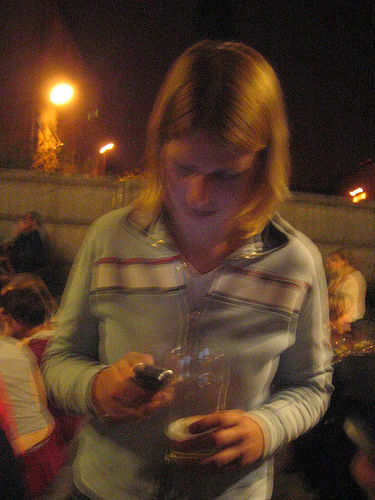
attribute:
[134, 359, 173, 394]
phone — silver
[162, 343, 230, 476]
glass — beer, held, small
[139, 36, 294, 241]
hair — blonde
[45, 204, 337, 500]
shirt — blue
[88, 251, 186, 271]
stripes — red, white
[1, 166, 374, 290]
fence — wooden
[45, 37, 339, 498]
person — sitting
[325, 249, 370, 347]
person — walking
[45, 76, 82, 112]
light — yellow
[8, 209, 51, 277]
guy — walking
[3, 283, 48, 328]
hair — brown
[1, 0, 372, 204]
sky — black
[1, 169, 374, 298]
wall — grey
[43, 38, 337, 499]
woman — blonde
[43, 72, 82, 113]
spotlight — bright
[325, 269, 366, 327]
shirt — white